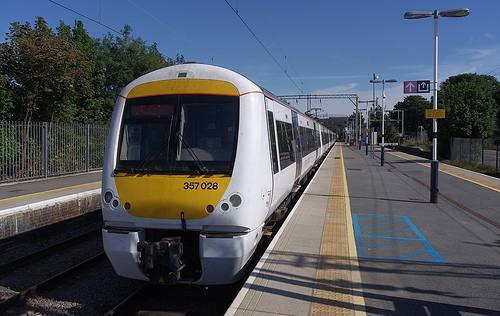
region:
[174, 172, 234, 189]
Black numbers on a bus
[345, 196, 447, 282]
Blue lines on the pavement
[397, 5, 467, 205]
Tall silver light post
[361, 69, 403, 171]
Tall silver light post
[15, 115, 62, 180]
Silver fence by the tracks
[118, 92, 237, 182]
Small windows to a bus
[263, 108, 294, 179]
Small windows to a bus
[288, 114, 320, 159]
Small windows to a bus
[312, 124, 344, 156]
Small windows to a bus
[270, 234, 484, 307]
Shadow cast by poles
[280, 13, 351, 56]
Beautiful blue sky above.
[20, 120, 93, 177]
Fence beside the train.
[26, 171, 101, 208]
Platform beside the train.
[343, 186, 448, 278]
Blue markings on the platform.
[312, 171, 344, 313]
Some bricks on the platform.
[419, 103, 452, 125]
Yellow sign on the light post.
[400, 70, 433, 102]
Signs pointing the way.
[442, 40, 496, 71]
A few white clouds in the sky.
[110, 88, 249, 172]
Large window on the train.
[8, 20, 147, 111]
Trees behind the fence.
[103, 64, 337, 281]
white and yellow train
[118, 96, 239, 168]
wind shield on train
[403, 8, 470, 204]
grey metal lamp post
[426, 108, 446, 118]
yellow sign on pole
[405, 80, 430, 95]
arrow signs on pole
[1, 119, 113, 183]
grey metal fence by tracks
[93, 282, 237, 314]
metal and wood train tracks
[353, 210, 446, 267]
blue lines on sidewalk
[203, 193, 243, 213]
head lights on train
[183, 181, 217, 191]
black numbers on train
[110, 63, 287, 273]
yellow and white train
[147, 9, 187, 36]
white clouds in blue sky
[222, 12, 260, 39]
white clouds in blue sky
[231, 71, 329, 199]
white train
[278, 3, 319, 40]
white clouds in blue sky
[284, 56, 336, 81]
white clouds in blue sky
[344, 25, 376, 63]
white clouds in blue sky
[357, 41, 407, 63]
white clouds in blue sky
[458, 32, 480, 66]
white clouds in blue sky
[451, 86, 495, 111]
green leaves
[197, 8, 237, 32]
white clouds in blue sky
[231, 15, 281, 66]
white clouds in blue sky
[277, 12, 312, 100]
white clouds in blue sky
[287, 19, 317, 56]
white clouds in blue sky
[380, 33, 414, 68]
white clouds in blue sky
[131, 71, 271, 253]
yellow and white light rail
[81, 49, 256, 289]
yellow and white passenger train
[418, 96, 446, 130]
yellow and black sign